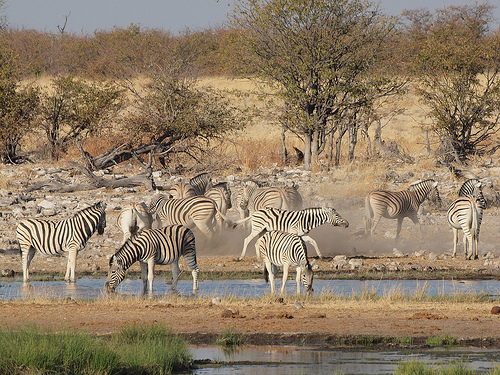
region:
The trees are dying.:
[11, 14, 478, 83]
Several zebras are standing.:
[3, 142, 496, 282]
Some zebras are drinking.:
[29, 199, 344, 309]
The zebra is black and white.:
[93, 232, 218, 298]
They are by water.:
[13, 216, 497, 311]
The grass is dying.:
[140, 55, 305, 177]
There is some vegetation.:
[15, 315, 195, 374]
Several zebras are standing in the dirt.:
[13, 184, 498, 281]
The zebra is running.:
[350, 173, 438, 270]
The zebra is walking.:
[228, 187, 360, 270]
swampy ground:
[172, 330, 495, 374]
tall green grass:
[2, 322, 184, 372]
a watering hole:
[5, 263, 498, 308]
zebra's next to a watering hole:
[10, 169, 491, 297]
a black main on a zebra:
[295, 234, 312, 270]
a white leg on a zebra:
[144, 253, 155, 296]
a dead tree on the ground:
[25, 160, 160, 194]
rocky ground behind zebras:
[6, 163, 341, 228]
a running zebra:
[240, 203, 351, 261]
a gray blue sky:
[4, 0, 499, 45]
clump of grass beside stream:
[10, 327, 192, 372]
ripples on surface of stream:
[331, 344, 398, 374]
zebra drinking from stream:
[247, 232, 322, 298]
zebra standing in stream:
[5, 200, 105, 295]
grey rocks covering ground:
[30, 190, 75, 211]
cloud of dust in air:
[321, 230, 369, 255]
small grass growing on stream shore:
[385, 329, 457, 349]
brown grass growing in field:
[243, 128, 276, 167]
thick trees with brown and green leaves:
[7, 28, 232, 74]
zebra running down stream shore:
[245, 198, 349, 236]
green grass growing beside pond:
[97, 327, 202, 367]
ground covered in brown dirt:
[333, 308, 398, 334]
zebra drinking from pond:
[253, 232, 324, 297]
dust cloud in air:
[326, 228, 383, 255]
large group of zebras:
[0, 145, 499, 307]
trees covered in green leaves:
[81, 15, 234, 76]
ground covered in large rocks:
[256, 165, 328, 183]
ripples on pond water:
[353, 349, 392, 374]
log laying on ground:
[27, 165, 164, 193]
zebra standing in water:
[2, 199, 108, 300]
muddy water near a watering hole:
[194, 339, 493, 373]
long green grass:
[0, 315, 193, 371]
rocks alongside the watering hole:
[336, 241, 449, 272]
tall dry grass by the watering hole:
[318, 274, 429, 304]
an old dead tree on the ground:
[31, 156, 173, 198]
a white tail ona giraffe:
[357, 190, 377, 222]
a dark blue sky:
[7, 2, 498, 34]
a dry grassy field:
[36, 64, 488, 132]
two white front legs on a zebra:
[62, 246, 79, 280]